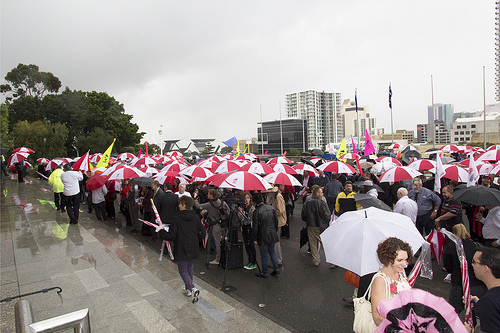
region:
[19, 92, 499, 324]
a crowd of people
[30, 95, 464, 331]
a crowd of people with umbrellas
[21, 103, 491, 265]
a crowd of white and red umbrellas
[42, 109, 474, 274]
a lot of red and white umbrellas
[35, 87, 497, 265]
a group of people in rainy weather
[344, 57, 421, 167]
a flag on a tall flag pole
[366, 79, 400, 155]
a tall flag pole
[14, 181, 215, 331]
a wet set of stairs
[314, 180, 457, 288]
someone with a white umbrella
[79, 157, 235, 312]
someone walking with closed umbrellas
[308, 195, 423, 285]
all white umbrella in bottom right corner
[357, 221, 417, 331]
woman with pink and black umbrella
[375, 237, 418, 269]
woman has curly brown hair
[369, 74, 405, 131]
flag on pole in background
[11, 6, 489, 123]
the sky is gray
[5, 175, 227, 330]
the ground is wet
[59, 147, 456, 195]
many red and white umbrellas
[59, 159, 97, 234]
man walking on sidewalk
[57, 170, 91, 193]
man is wearing a white shirt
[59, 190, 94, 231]
man is wearing black pants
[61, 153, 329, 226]
Red and white umbrellas on people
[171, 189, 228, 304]
Woman walking on a sidewalk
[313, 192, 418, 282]
White umbrella in a crowd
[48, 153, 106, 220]
People walking on a sidewalk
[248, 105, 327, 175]
Glass building in a town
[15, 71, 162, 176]
Trees by a road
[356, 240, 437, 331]
Woman in a crowd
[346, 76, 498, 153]
Four poles by a crowd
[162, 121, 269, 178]
Houses by a sidewalk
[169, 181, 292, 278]
People standing under umbrellas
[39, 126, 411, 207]
people are holding umbrellas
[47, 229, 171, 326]
the ground is wet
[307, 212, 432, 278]
the umbrella is white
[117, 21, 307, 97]
the sky is white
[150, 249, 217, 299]
the pants are purple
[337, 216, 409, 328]
woman is carrying a bag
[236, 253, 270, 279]
the shoes are green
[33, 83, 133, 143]
the trees are green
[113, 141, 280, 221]
the umbrellas are red and white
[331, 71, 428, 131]
the flags on poles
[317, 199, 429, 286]
solid white umbrella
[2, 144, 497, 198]
many identical red and white umbrellas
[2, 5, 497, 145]
sky is covered with rain clouds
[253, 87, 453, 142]
tall buildings in the background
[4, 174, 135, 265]
wet sidewalk shows people's reflections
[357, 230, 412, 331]
woman wearing white tank top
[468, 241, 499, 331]
man in front wearing a black shirt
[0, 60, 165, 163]
green trees in the background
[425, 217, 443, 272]
red and white umbrella not open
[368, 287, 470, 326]
pink and black umbrella partially opened